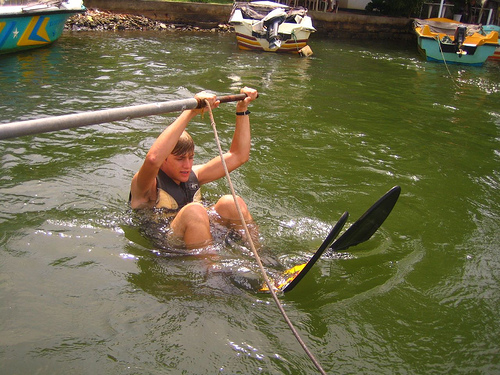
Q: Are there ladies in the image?
A: No, there are no ladies.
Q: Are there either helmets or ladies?
A: No, there are no ladies or helmets.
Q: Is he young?
A: Yes, the man is young.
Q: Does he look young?
A: Yes, the man is young.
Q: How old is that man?
A: The man is young.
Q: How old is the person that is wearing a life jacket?
A: The man is young.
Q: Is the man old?
A: No, the man is young.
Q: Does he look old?
A: No, the man is young.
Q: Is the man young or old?
A: The man is young.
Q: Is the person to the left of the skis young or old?
A: The man is young.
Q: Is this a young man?
A: Yes, this is a young man.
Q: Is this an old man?
A: No, this is a young man.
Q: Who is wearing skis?
A: The man is wearing skis.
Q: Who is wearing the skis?
A: The man is wearing skis.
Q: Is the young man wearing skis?
A: Yes, the man is wearing skis.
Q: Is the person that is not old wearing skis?
A: Yes, the man is wearing skis.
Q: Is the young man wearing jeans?
A: No, the man is wearing skis.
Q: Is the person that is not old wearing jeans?
A: No, the man is wearing skis.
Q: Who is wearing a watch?
A: The man is wearing a watch.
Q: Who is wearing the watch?
A: The man is wearing a watch.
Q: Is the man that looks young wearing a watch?
A: Yes, the man is wearing a watch.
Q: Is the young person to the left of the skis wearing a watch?
A: Yes, the man is wearing a watch.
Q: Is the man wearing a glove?
A: No, the man is wearing a watch.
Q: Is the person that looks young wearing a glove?
A: No, the man is wearing a watch.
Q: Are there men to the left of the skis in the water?
A: Yes, there is a man to the left of the skis.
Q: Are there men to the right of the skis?
A: No, the man is to the left of the skis.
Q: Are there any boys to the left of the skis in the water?
A: No, there is a man to the left of the skis.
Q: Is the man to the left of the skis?
A: Yes, the man is to the left of the skis.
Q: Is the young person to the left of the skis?
A: Yes, the man is to the left of the skis.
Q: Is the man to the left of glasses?
A: No, the man is to the left of the skis.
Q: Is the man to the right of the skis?
A: No, the man is to the left of the skis.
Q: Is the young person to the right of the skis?
A: No, the man is to the left of the skis.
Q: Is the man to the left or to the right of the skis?
A: The man is to the left of the skis.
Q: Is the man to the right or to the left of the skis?
A: The man is to the left of the skis.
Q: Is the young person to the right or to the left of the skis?
A: The man is to the left of the skis.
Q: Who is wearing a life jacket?
A: The man is wearing a life jacket.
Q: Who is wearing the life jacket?
A: The man is wearing a life jacket.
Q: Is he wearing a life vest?
A: Yes, the man is wearing a life vest.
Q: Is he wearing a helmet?
A: No, the man is wearing a life vest.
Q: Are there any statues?
A: No, there are no statues.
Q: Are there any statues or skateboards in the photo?
A: No, there are no statues or skateboards.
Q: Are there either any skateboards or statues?
A: No, there are no statues or skateboards.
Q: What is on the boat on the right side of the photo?
A: The rope is on the boat.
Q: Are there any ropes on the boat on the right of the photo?
A: Yes, there is a rope on the boat.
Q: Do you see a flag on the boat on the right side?
A: No, there is a rope on the boat.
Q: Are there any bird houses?
A: No, there are no bird houses.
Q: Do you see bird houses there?
A: No, there are no bird houses.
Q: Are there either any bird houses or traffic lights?
A: No, there are no bird houses or traffic lights.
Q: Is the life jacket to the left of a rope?
A: Yes, the life jacket is to the left of a rope.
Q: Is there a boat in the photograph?
A: Yes, there is a boat.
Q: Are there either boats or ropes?
A: Yes, there is a boat.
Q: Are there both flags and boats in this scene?
A: No, there is a boat but no flags.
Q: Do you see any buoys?
A: No, there are no buoys.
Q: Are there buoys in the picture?
A: No, there are no buoys.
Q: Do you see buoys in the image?
A: No, there are no buoys.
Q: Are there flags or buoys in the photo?
A: No, there are no buoys or flags.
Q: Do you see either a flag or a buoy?
A: No, there are no buoys or flags.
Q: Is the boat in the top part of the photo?
A: Yes, the boat is in the top of the image.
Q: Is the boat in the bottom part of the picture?
A: No, the boat is in the top of the image.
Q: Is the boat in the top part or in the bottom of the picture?
A: The boat is in the top of the image.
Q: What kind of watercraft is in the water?
A: The watercraft is a boat.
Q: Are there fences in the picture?
A: No, there are no fences.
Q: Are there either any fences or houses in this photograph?
A: No, there are no fences or houses.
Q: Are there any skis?
A: Yes, there are skis.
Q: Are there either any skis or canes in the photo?
A: Yes, there are skis.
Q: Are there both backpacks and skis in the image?
A: No, there are skis but no backpacks.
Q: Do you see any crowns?
A: No, there are no crowns.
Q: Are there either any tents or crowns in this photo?
A: No, there are no crowns or tents.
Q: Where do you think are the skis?
A: The skis are in the water.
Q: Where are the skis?
A: The skis are in the water.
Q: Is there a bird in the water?
A: No, there are skis in the water.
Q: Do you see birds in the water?
A: No, there are skis in the water.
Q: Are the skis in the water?
A: Yes, the skis are in the water.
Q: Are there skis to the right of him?
A: Yes, there are skis to the right of the man.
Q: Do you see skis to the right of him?
A: Yes, there are skis to the right of the man.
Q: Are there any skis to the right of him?
A: Yes, there are skis to the right of the man.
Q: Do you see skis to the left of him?
A: No, the skis are to the right of the man.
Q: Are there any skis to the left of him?
A: No, the skis are to the right of the man.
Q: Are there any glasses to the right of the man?
A: No, there are skis to the right of the man.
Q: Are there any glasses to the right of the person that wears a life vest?
A: No, there are skis to the right of the man.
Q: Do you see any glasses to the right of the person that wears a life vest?
A: No, there are skis to the right of the man.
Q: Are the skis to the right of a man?
A: Yes, the skis are to the right of a man.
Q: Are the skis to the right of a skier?
A: No, the skis are to the right of a man.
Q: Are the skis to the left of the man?
A: No, the skis are to the right of the man.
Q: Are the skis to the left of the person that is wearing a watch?
A: No, the skis are to the right of the man.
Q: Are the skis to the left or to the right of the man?
A: The skis are to the right of the man.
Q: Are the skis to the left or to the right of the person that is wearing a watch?
A: The skis are to the right of the man.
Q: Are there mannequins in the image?
A: No, there are no mannequins.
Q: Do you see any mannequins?
A: No, there are no mannequins.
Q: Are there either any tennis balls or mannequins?
A: No, there are no mannequins or tennis balls.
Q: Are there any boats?
A: Yes, there is a boat.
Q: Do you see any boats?
A: Yes, there is a boat.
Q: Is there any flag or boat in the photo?
A: Yes, there is a boat.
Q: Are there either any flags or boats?
A: Yes, there is a boat.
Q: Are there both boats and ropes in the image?
A: Yes, there are both a boat and a rope.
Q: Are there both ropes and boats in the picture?
A: Yes, there are both a boat and a rope.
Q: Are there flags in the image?
A: No, there are no flags.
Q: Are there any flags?
A: No, there are no flags.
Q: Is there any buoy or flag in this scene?
A: No, there are no flags or buoys.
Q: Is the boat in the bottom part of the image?
A: No, the boat is in the top of the image.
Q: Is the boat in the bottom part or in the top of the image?
A: The boat is in the top of the image.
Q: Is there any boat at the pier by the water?
A: Yes, there is a boat at the pier.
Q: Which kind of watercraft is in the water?
A: The watercraft is a boat.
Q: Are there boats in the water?
A: Yes, there is a boat in the water.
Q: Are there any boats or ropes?
A: Yes, there is a boat.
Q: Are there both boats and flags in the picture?
A: No, there is a boat but no flags.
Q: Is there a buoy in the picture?
A: No, there are no buoys.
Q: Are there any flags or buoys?
A: No, there are no buoys or flags.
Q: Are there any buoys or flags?
A: No, there are no buoys or flags.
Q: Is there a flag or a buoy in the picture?
A: No, there are no buoys or flags.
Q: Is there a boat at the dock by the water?
A: Yes, there is a boat at the pier.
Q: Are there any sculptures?
A: No, there are no sculptures.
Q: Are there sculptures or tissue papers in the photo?
A: No, there are no sculptures or tissue papers.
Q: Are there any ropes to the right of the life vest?
A: Yes, there is a rope to the right of the life vest.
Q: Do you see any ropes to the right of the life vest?
A: Yes, there is a rope to the right of the life vest.